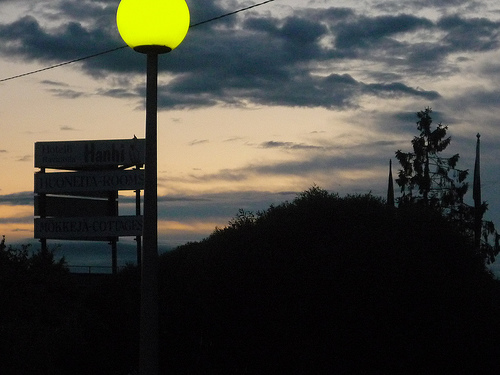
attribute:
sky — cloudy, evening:
[290, 51, 370, 153]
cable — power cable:
[0, 0, 273, 88]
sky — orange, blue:
[1, 1, 498, 278]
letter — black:
[83, 170, 96, 189]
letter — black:
[81, 140, 96, 166]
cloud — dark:
[11, 1, 473, 108]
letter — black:
[98, 172, 114, 187]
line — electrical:
[0, 0, 277, 84]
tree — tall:
[386, 97, 498, 265]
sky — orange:
[16, 10, 496, 235]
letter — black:
[31, 167, 51, 195]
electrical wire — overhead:
[4, 0, 261, 92]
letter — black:
[99, 140, 130, 165]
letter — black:
[80, 145, 155, 160]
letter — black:
[86, 144, 107, 165]